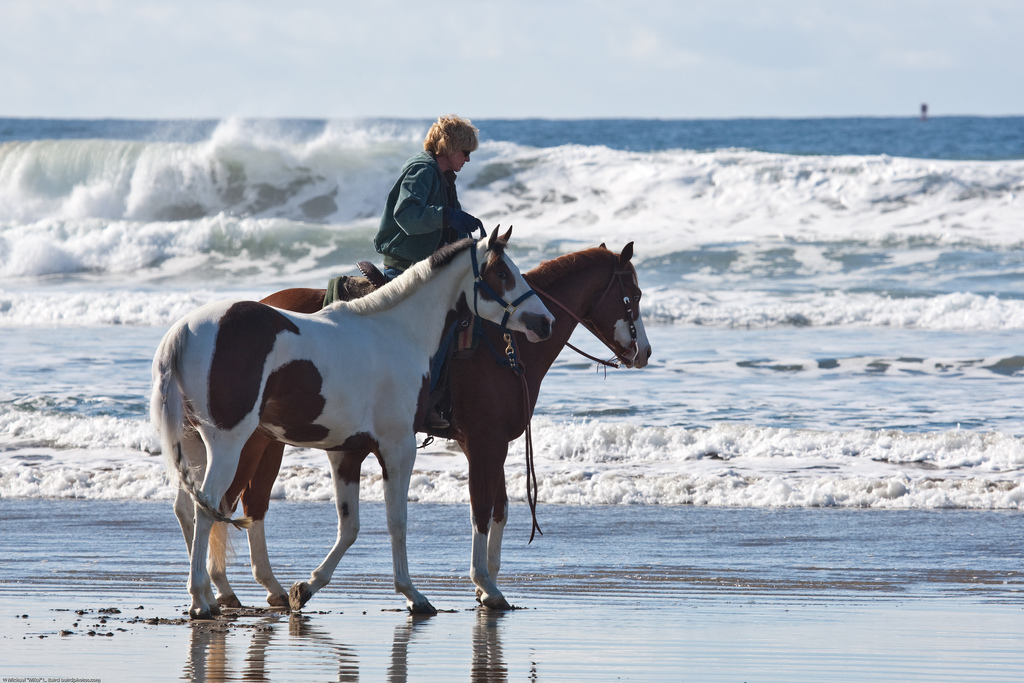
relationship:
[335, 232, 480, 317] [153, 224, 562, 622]
mane growing on horse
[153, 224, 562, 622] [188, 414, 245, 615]
horse has legs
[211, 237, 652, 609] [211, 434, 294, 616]
horse has legs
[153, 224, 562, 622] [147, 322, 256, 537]
horse has tail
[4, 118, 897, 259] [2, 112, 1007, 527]
waves in ocean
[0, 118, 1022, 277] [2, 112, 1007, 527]
waves in ocean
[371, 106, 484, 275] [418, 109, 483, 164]
woman has blond hair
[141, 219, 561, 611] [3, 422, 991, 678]
white/brown horse on beach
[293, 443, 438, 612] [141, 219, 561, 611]
front legs of white/brown horse